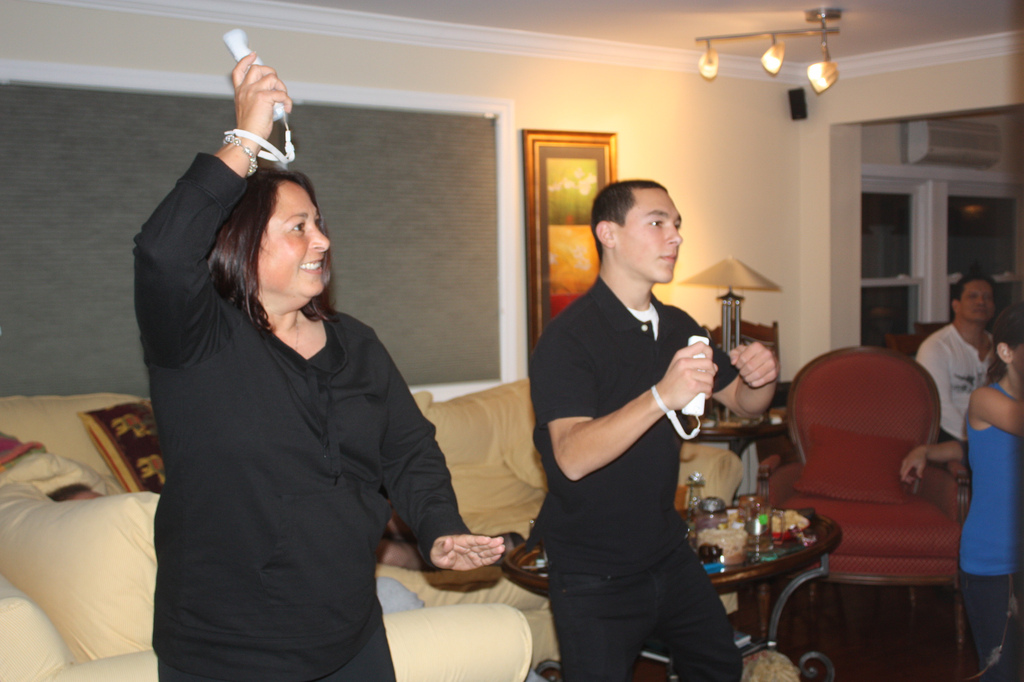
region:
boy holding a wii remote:
[537, 174, 716, 631]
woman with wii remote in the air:
[139, 16, 449, 678]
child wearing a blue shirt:
[951, 310, 1021, 573]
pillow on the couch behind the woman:
[71, 402, 158, 495]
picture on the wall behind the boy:
[504, 104, 607, 323]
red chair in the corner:
[747, 344, 981, 610]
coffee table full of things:
[713, 487, 834, 586]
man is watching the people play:
[916, 253, 1000, 440]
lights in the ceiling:
[689, 29, 852, 115]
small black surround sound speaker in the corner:
[777, 81, 810, 130]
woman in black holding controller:
[134, 51, 505, 680]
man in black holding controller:
[525, 177, 779, 680]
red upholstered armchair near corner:
[768, 345, 975, 658]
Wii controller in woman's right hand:
[220, 23, 296, 164]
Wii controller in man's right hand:
[648, 332, 718, 440]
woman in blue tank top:
[952, 300, 1022, 678]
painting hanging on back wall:
[516, 129, 618, 367]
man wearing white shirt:
[906, 268, 1005, 442]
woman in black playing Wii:
[136, 26, 504, 679]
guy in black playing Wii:
[538, 181, 777, 676]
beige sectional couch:
[4, 376, 739, 680]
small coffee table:
[507, 505, 831, 680]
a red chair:
[770, 353, 968, 658]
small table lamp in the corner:
[689, 256, 772, 348]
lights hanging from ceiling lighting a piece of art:
[699, 16, 846, 93]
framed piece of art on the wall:
[520, 130, 612, 346]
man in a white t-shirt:
[918, 278, 996, 441]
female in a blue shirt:
[959, 315, 1017, 679]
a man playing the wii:
[561, 159, 830, 574]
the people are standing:
[126, 22, 809, 551]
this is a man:
[487, 162, 838, 656]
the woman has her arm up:
[108, 150, 304, 521]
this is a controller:
[186, 32, 367, 214]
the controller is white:
[179, 32, 445, 304]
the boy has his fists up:
[493, 243, 807, 623]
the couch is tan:
[29, 447, 159, 666]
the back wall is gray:
[340, 164, 493, 330]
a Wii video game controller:
[218, 26, 294, 119]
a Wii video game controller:
[678, 334, 708, 414]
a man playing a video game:
[526, 171, 782, 675]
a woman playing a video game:
[128, 23, 506, 678]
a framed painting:
[517, 125, 617, 366]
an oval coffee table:
[501, 492, 841, 679]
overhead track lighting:
[691, 17, 840, 95]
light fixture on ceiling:
[696, 26, 728, 85]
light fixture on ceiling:
[738, 21, 786, 89]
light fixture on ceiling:
[792, 17, 847, 113]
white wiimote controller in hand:
[201, 23, 304, 188]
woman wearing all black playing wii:
[140, 16, 514, 678]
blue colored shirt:
[956, 392, 1018, 574]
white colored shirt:
[911, 318, 1016, 436]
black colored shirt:
[522, 274, 728, 521]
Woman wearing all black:
[121, 26, 510, 678]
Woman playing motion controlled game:
[128, 21, 509, 680]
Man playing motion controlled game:
[529, 176, 782, 677]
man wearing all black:
[531, 173, 781, 679]